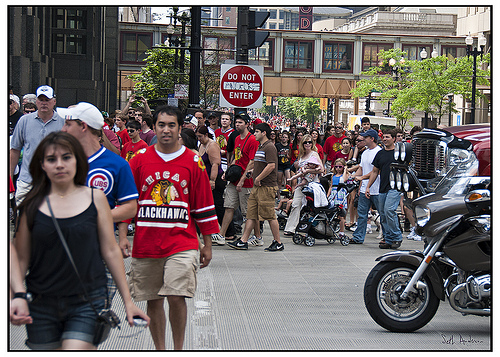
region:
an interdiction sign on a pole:
[211, 54, 272, 116]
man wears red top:
[125, 96, 225, 350]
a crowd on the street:
[200, 105, 405, 242]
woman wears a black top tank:
[20, 131, 137, 343]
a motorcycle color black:
[356, 145, 491, 332]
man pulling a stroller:
[286, 125, 383, 243]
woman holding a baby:
[286, 130, 326, 228]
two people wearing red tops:
[208, 109, 253, 182]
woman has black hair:
[16, 128, 127, 345]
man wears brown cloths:
[239, 120, 287, 256]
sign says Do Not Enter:
[221, 64, 263, 108]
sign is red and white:
[220, 65, 265, 108]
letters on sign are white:
[221, 63, 264, 110]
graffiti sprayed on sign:
[223, 80, 260, 91]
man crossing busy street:
[135, 103, 218, 348]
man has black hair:
[121, 100, 227, 346]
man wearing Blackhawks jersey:
[124, 107, 230, 349]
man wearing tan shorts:
[116, 84, 225, 349]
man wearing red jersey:
[126, 98, 215, 352]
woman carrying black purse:
[26, 128, 128, 355]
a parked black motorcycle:
[364, 140, 488, 332]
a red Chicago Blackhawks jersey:
[125, 143, 221, 263]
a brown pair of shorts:
[126, 250, 197, 297]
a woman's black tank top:
[24, 184, 107, 296]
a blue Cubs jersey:
[83, 143, 139, 205]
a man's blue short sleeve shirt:
[11, 107, 63, 187]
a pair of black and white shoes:
[222, 234, 251, 251]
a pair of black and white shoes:
[263, 237, 285, 252]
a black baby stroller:
[289, 178, 356, 246]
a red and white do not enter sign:
[219, 60, 263, 110]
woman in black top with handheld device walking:
[15, 134, 153, 354]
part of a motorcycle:
[358, 178, 495, 338]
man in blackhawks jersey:
[126, 103, 226, 355]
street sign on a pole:
[216, 11, 269, 108]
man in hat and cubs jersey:
[55, 97, 143, 246]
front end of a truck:
[403, 112, 494, 212]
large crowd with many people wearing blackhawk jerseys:
[111, 108, 401, 203]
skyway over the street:
[116, 21, 498, 100]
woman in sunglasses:
[292, 132, 321, 187]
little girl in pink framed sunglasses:
[324, 153, 359, 237]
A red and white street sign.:
[219, 63, 264, 108]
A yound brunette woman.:
[9, 129, 149, 351]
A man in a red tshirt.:
[117, 103, 222, 353]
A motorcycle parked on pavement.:
[363, 148, 499, 331]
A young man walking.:
[363, 127, 403, 248]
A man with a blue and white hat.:
[9, 83, 64, 217]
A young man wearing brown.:
[226, 122, 285, 252]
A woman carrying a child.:
[281, 134, 324, 236]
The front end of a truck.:
[406, 122, 491, 205]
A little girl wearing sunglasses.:
[326, 155, 351, 238]